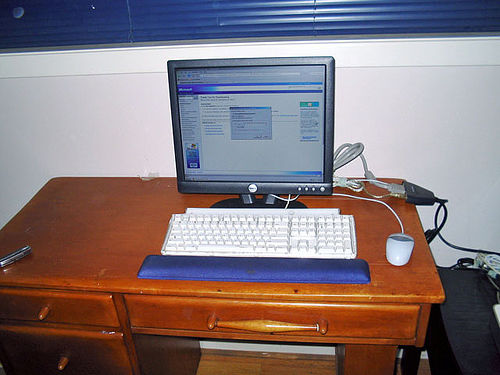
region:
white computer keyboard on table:
[161, 213, 359, 259]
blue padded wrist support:
[140, 256, 369, 284]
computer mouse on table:
[389, 231, 414, 267]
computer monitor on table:
[166, 57, 336, 195]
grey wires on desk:
[334, 140, 404, 201]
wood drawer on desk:
[126, 295, 421, 341]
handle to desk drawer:
[208, 315, 328, 336]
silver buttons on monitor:
[297, 184, 327, 194]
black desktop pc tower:
[433, 267, 498, 374]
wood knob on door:
[34, 308, 49, 320]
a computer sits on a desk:
[12, 47, 424, 292]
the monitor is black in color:
[162, 48, 349, 205]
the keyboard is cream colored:
[159, 202, 364, 261]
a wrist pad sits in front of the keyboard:
[139, 252, 375, 289]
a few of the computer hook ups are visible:
[340, 138, 474, 240]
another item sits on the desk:
[2, 231, 40, 277]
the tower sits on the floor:
[423, 260, 491, 372]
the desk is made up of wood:
[10, 158, 430, 373]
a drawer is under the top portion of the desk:
[120, 293, 430, 353]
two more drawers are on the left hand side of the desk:
[0, 289, 137, 374]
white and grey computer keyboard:
[163, 212, 357, 259]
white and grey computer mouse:
[386, 230, 413, 267]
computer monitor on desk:
[166, 55, 334, 195]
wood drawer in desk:
[123, 294, 420, 344]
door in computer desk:
[3, 288, 123, 333]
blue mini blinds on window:
[1, 2, 498, 53]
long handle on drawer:
[206, 315, 327, 334]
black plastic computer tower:
[431, 265, 498, 372]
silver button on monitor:
[248, 183, 256, 193]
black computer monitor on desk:
[163, 42, 338, 203]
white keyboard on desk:
[171, 203, 348, 275]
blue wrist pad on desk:
[141, 258, 367, 283]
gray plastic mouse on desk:
[384, 228, 415, 267]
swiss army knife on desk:
[1, 234, 37, 259]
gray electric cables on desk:
[334, 145, 370, 195]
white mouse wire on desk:
[345, 183, 425, 228]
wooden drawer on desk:
[123, 298, 416, 342]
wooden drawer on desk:
[2, 292, 120, 322]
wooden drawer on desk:
[5, 330, 122, 373]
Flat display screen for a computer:
[166, 57, 333, 196]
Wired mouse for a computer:
[384, 231, 413, 267]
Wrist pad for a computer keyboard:
[136, 254, 369, 284]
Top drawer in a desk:
[0, 287, 122, 334]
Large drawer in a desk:
[121, 292, 423, 346]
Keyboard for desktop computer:
[159, 207, 356, 258]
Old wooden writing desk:
[0, 174, 446, 374]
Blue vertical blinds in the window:
[0, 0, 499, 50]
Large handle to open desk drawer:
[206, 313, 328, 337]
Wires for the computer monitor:
[332, 142, 407, 199]